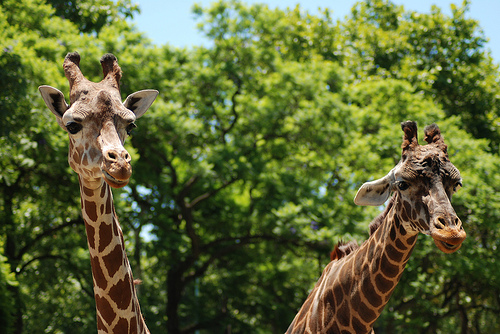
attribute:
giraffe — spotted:
[37, 51, 159, 333]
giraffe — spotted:
[284, 120, 467, 334]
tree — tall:
[164, 161, 245, 333]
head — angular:
[37, 50, 160, 190]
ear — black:
[40, 84, 68, 121]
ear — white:
[354, 174, 396, 207]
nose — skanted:
[103, 149, 131, 163]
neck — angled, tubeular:
[329, 192, 419, 332]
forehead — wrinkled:
[402, 146, 449, 175]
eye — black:
[126, 123, 135, 137]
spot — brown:
[90, 256, 107, 290]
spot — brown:
[361, 265, 382, 311]